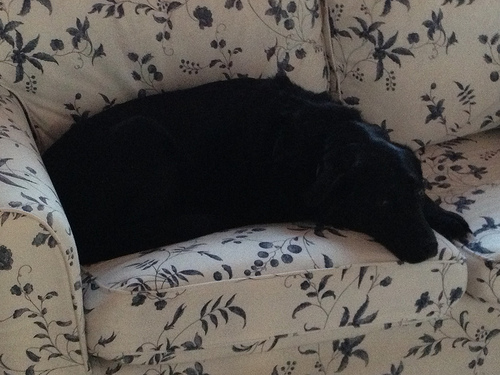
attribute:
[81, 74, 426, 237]
dog — black, laying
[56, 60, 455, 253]
dog — black, sleeping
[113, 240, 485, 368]
couch — white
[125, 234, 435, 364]
couch — blue, floral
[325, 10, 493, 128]
cushion — center, back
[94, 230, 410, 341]
seat — cushioned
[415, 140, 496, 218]
seat — cushioned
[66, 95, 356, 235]
dog — black, lying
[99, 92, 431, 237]
dog — lying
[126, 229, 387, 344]
cushion — top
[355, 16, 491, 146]
cushion — top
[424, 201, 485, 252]
paw — black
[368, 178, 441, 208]
eyes — black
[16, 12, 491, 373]
couch — one, flowered, white, blue, patterned 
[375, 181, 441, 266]
face — one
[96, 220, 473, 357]
cushion — one, couch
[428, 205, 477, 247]
paw — one, canine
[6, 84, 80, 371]
arm — couch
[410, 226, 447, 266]
snout — long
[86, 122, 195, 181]
fur — black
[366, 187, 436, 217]
eyes — black, canine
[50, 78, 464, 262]
dog — black , one, furry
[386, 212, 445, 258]
snout — long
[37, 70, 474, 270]
dog — sleeping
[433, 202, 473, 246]
paw — his, out